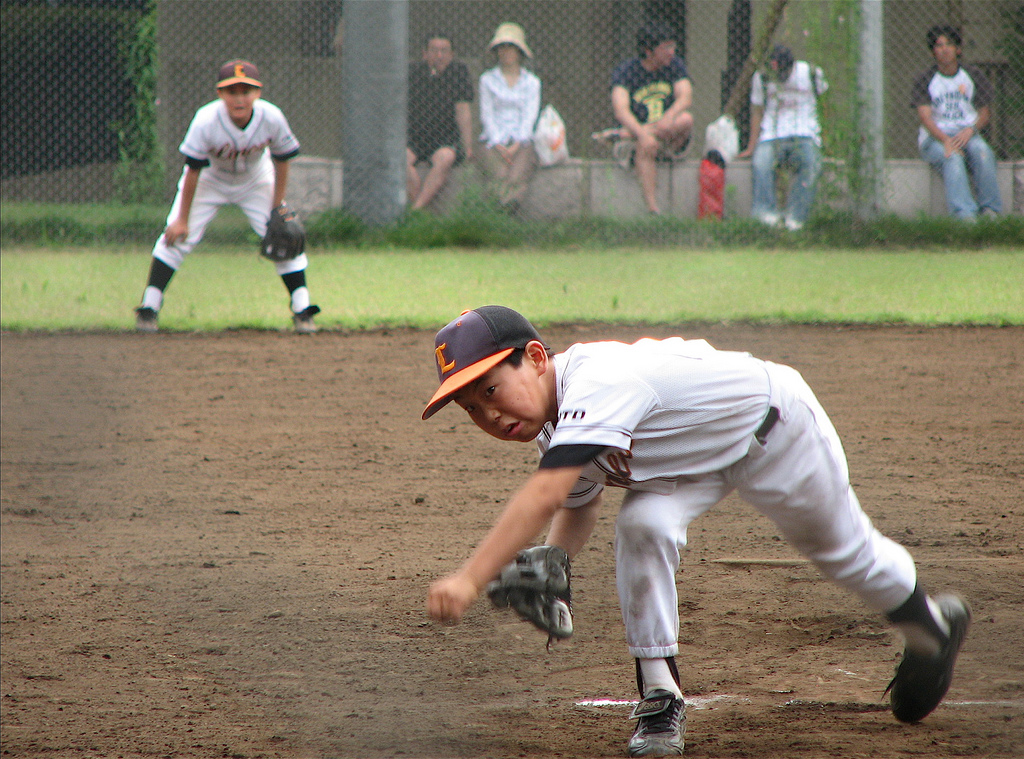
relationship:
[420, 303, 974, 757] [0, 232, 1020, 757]
boy standing in a field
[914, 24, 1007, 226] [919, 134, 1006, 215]
man wearing jeans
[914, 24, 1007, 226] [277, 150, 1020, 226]
man sitting on wall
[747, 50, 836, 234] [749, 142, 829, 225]
man wearing jeans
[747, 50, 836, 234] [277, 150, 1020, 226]
man sitting on wall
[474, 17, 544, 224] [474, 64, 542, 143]
woman wearing a shirt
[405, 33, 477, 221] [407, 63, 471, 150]
man wearing a shirt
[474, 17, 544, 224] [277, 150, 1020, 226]
woman sitting on wall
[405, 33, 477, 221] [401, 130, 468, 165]
man wearing shorts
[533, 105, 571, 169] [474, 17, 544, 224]
bag next to woman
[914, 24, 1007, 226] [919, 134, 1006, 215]
man wearing blue jeans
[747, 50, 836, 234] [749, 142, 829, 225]
man wearing blue jeans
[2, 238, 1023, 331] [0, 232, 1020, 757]
grass on field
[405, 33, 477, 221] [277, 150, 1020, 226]
man sitting on wall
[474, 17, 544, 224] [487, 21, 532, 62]
woman wearing a hat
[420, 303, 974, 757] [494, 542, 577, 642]
boy wearing a glove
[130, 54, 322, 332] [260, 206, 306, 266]
boy wearing a glove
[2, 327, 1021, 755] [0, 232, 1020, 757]
dirt on field